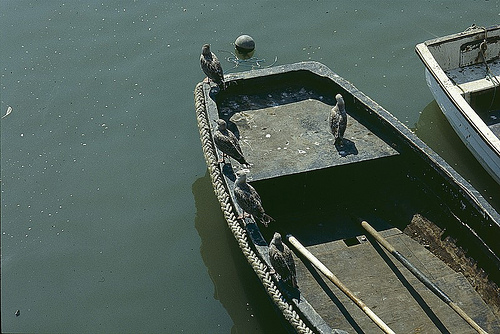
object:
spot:
[20, 73, 29, 79]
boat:
[409, 23, 500, 181]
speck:
[369, 56, 375, 61]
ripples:
[19, 132, 28, 139]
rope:
[191, 82, 315, 333]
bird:
[195, 41, 229, 92]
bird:
[327, 93, 349, 145]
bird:
[228, 168, 277, 228]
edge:
[191, 77, 315, 333]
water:
[0, 0, 500, 333]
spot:
[57, 203, 65, 208]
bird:
[211, 115, 253, 167]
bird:
[266, 230, 300, 292]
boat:
[195, 58, 500, 330]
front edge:
[188, 58, 326, 83]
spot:
[19, 132, 27, 139]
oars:
[286, 232, 396, 333]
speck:
[0, 101, 14, 120]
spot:
[117, 121, 126, 126]